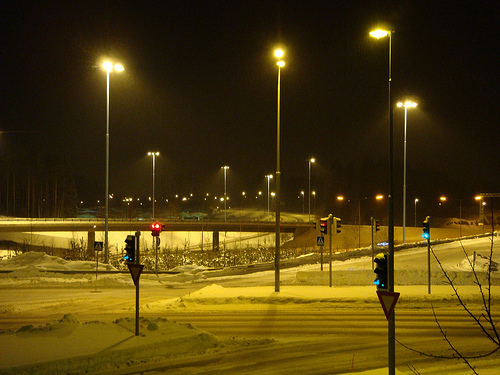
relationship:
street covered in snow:
[3, 216, 496, 373] [155, 282, 496, 307]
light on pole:
[149, 221, 155, 231] [145, 215, 162, 273]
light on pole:
[153, 219, 162, 231] [145, 215, 162, 273]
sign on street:
[93, 241, 103, 279] [3, 216, 496, 373]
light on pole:
[154, 222, 162, 230] [152, 230, 162, 272]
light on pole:
[150, 224, 154, 230] [152, 230, 162, 272]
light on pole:
[154, 222, 162, 230] [153, 235, 160, 275]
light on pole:
[150, 224, 154, 230] [153, 235, 160, 275]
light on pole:
[150, 224, 154, 230] [151, 220, 161, 272]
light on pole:
[150, 224, 154, 230] [149, 231, 166, 277]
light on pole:
[154, 222, 162, 230] [154, 237, 159, 272]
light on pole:
[150, 224, 154, 230] [154, 237, 159, 272]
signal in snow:
[120, 229, 140, 263] [7, 311, 227, 365]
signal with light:
[120, 229, 140, 263] [122, 252, 137, 266]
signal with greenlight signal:
[369, 251, 390, 291] [373, 252, 387, 287]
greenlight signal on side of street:
[123, 235, 135, 262] [6, 270, 498, 336]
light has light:
[150, 224, 154, 230] [148, 219, 161, 239]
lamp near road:
[92, 44, 375, 74] [13, 265, 476, 367]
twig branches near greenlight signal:
[395, 209, 497, 372] [373, 252, 387, 287]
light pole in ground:
[140, 141, 170, 252] [273, 83, 381, 121]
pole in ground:
[217, 165, 233, 214] [7, 237, 498, 373]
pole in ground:
[86, 50, 128, 272] [84, 262, 123, 284]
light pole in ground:
[270, 42, 289, 294] [1, 223, 498, 371]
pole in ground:
[361, 10, 401, 314] [1, 223, 498, 371]